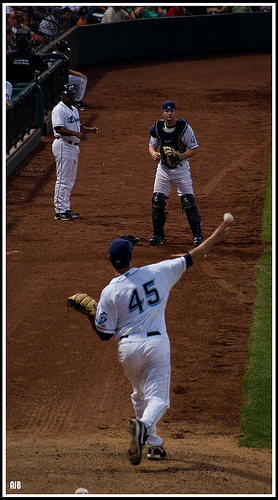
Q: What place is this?
A: It is a field.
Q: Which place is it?
A: It is a field.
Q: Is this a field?
A: Yes, it is a field.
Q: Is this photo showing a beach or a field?
A: It is showing a field.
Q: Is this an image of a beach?
A: No, the picture is showing a field.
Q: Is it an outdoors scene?
A: Yes, it is outdoors.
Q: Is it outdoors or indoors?
A: It is outdoors.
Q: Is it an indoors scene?
A: No, it is outdoors.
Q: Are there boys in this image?
A: No, there are no boys.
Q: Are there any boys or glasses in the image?
A: No, there are no boys or glasses.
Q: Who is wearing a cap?
A: The catcher is wearing a cap.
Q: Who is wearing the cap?
A: The catcher is wearing a cap.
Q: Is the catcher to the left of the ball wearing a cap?
A: Yes, the catcher is wearing a cap.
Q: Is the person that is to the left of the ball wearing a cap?
A: Yes, the catcher is wearing a cap.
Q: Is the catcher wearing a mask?
A: No, the catcher is wearing a cap.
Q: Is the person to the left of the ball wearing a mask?
A: No, the catcher is wearing a cap.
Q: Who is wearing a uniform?
A: The catcher is wearing a uniform.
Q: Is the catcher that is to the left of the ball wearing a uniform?
A: Yes, the catcher is wearing a uniform.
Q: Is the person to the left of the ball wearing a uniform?
A: Yes, the catcher is wearing a uniform.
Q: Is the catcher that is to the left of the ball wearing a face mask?
A: No, the catcher is wearing a uniform.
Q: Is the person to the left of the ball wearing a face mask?
A: No, the catcher is wearing a uniform.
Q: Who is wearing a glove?
A: The catcher is wearing a glove.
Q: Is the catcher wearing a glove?
A: Yes, the catcher is wearing a glove.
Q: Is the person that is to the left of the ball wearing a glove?
A: Yes, the catcher is wearing a glove.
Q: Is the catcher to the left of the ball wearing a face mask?
A: No, the catcher is wearing a glove.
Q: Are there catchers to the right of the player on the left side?
A: Yes, there is a catcher to the right of the player.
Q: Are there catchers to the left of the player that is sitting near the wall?
A: No, the catcher is to the right of the player.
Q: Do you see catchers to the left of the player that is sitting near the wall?
A: No, the catcher is to the right of the player.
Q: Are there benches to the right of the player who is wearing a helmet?
A: No, there is a catcher to the right of the player.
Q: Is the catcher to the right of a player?
A: Yes, the catcher is to the right of a player.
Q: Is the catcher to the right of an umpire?
A: No, the catcher is to the right of a player.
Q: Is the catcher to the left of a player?
A: No, the catcher is to the right of a player.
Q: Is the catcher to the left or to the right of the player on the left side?
A: The catcher is to the right of the player.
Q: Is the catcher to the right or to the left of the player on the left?
A: The catcher is to the right of the player.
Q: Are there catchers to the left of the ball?
A: Yes, there is a catcher to the left of the ball.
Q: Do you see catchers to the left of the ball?
A: Yes, there is a catcher to the left of the ball.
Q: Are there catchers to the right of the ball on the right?
A: No, the catcher is to the left of the ball.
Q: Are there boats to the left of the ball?
A: No, there is a catcher to the left of the ball.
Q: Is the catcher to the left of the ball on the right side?
A: Yes, the catcher is to the left of the ball.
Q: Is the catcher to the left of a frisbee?
A: No, the catcher is to the left of the ball.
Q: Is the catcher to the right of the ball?
A: No, the catcher is to the left of the ball.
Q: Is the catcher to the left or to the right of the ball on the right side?
A: The catcher is to the left of the ball.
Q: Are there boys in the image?
A: No, there are no boys.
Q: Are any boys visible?
A: No, there are no boys.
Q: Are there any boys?
A: No, there are no boys.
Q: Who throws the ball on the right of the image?
A: The player throws the ball.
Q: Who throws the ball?
A: The player throws the ball.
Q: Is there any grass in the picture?
A: Yes, there is grass.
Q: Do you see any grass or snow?
A: Yes, there is grass.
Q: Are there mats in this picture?
A: No, there are no mats.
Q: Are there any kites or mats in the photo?
A: No, there are no mats or kites.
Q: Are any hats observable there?
A: Yes, there is a hat.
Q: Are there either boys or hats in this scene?
A: Yes, there is a hat.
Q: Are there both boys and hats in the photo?
A: No, there is a hat but no boys.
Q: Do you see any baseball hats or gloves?
A: Yes, there is a baseball hat.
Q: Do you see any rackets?
A: No, there are no rackets.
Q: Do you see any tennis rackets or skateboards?
A: No, there are no tennis rackets or skateboards.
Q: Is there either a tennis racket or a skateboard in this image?
A: No, there are no rackets or skateboards.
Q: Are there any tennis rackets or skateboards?
A: No, there are no tennis rackets or skateboards.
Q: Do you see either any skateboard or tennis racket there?
A: No, there are no rackets or skateboards.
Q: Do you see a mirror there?
A: No, there are no mirrors.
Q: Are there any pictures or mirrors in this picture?
A: No, there are no mirrors or pictures.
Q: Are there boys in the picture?
A: No, there are no boys.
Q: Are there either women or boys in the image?
A: No, there are no boys or women.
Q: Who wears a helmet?
A: The player wears a helmet.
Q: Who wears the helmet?
A: The player wears a helmet.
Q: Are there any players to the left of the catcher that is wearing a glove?
A: Yes, there is a player to the left of the catcher.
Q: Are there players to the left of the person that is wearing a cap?
A: Yes, there is a player to the left of the catcher.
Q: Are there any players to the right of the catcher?
A: No, the player is to the left of the catcher.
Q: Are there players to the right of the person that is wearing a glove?
A: No, the player is to the left of the catcher.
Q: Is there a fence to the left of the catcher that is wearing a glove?
A: No, there is a player to the left of the catcher.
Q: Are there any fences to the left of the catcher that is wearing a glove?
A: No, there is a player to the left of the catcher.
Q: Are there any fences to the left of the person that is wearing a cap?
A: No, there is a player to the left of the catcher.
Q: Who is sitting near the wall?
A: The player is sitting near the wall.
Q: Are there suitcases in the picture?
A: No, there are no suitcases.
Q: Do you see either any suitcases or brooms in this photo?
A: No, there are no suitcases or brooms.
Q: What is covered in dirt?
A: The ground is covered in dirt.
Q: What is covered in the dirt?
A: The ground is covered in dirt.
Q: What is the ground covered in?
A: The ground is covered in dirt.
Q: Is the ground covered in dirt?
A: Yes, the ground is covered in dirt.